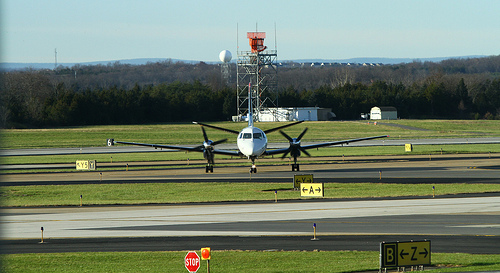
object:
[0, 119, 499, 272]
field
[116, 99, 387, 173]
plane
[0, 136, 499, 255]
runway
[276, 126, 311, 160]
propellers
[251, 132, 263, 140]
windshield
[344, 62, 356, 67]
building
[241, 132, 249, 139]
window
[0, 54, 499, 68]
mountains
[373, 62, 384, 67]
buildings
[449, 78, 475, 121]
trees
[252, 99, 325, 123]
buildings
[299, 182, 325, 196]
sign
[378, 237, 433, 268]
sign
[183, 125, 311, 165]
twin propeller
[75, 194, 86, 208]
runway marker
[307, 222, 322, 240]
runway marker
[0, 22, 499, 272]
airport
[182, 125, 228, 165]
propeller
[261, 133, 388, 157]
wings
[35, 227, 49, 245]
light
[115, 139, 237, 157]
wing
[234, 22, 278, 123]
communication tower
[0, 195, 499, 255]
pavement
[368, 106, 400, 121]
barn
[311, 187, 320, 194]
arrows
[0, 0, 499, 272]
area